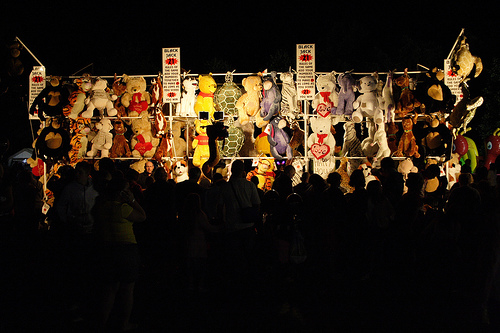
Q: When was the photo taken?
A: Night.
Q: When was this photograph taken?
A: Night.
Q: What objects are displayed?
A: Stuffed animals.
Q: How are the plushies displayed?
A: Hanging from racks.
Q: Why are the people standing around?
A: Looking at the plushies.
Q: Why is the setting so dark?
A: The scene is outside at night.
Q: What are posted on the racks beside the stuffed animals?
A: Signs.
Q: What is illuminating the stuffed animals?
A: Light.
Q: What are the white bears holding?
A: Hearts.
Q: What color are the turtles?
A: Green.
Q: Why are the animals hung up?
A: To be displayed and sold.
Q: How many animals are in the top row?
A: Nineteen.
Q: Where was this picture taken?
A: A stuffed animal toy cart.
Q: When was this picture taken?
A: At night.